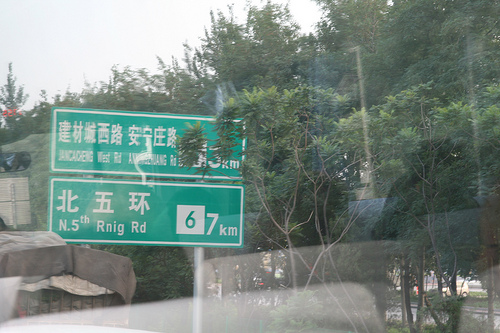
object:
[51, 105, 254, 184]
sign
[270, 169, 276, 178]
leaf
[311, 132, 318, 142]
leaf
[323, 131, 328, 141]
leaf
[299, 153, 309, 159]
leaf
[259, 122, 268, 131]
leaf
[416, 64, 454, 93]
leaves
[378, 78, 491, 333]
tree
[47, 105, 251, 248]
highway sign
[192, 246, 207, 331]
metal pole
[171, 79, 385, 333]
trees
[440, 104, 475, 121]
leaves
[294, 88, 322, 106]
leaves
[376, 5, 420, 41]
leaves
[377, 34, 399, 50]
green leaves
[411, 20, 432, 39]
green leaves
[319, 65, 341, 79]
green leaves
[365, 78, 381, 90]
green leaves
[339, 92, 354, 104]
green leaves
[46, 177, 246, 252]
sign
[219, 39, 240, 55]
leaves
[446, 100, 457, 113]
leaf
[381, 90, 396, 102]
leaf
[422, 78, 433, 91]
leaf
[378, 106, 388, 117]
leaf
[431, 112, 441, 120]
leaf